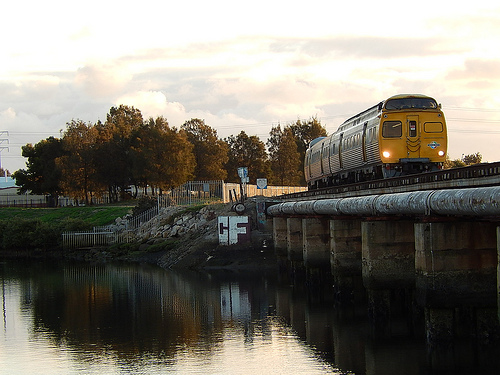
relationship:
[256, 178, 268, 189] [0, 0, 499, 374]
sign in shot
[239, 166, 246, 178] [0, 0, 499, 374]
sign in shot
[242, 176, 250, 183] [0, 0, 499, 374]
sign in shot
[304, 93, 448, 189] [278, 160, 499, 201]
train on tracks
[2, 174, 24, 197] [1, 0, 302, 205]
building in background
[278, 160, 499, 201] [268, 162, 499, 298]
tracks on bridge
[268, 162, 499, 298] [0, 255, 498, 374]
bridge over water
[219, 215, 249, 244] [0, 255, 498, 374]
cf near water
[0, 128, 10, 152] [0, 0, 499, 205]
pole in distance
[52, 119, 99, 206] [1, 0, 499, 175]
tree against sky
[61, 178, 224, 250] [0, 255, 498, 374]
fence down to water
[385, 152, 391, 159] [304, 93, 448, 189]
light on train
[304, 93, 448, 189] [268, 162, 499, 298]
train on bridge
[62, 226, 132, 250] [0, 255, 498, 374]
gate separating water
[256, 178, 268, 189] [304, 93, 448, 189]
sign for train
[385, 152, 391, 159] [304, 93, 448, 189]
light of train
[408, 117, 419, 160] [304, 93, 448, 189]
door for train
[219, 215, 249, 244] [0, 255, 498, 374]
cf above water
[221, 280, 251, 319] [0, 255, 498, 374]
reflection in water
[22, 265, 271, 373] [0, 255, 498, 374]
reflection in water